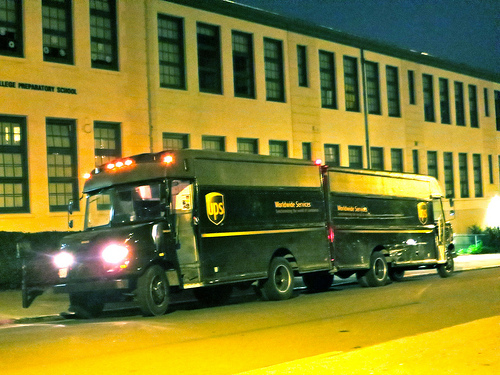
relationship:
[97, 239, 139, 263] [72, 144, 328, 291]
lights on truck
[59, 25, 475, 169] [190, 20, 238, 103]
building has window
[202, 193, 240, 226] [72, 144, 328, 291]
logo on truck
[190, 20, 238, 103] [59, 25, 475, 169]
window on building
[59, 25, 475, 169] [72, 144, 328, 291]
building near truck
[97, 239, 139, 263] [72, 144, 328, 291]
lights are on truck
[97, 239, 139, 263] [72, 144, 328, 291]
lights in front of truck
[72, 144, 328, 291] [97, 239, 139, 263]
truck has lights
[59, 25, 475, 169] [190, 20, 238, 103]
building with window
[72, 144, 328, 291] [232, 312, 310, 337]
truck on road